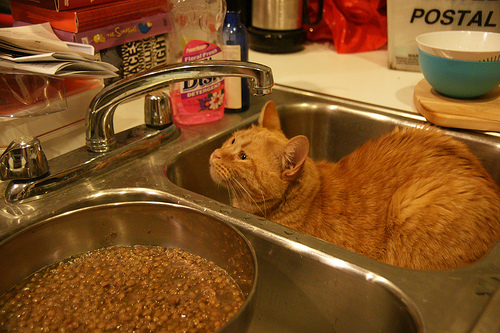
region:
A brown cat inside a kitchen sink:
[223, 111, 457, 240]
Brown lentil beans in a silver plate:
[30, 222, 293, 329]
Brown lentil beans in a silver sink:
[6, 210, 366, 331]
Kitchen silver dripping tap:
[87, 53, 277, 149]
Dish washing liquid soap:
[176, 9, 226, 124]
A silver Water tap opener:
[6, 131, 53, 180]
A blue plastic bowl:
[415, 55, 497, 97]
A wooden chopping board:
[421, 83, 498, 137]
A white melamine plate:
[416, 29, 498, 56]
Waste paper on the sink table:
[3, 26, 108, 83]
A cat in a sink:
[156, 50, 485, 301]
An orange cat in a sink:
[154, 58, 484, 271]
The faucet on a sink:
[79, 38, 319, 204]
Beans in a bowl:
[29, 192, 243, 332]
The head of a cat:
[194, 93, 330, 218]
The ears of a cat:
[257, 93, 310, 196]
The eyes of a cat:
[218, 123, 259, 172]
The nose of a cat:
[197, 139, 232, 179]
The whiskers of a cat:
[197, 149, 276, 221]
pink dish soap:
[158, 20, 244, 161]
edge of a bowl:
[244, 261, 262, 292]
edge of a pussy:
[367, 117, 439, 171]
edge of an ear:
[293, 137, 309, 192]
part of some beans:
[188, 252, 225, 297]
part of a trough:
[146, 180, 189, 229]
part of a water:
[171, 261, 203, 301]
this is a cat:
[210, 110, 448, 200]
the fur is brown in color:
[372, 149, 454, 236]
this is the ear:
[286, 131, 313, 168]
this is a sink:
[349, 275, 450, 319]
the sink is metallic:
[356, 267, 447, 325]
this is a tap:
[159, 52, 276, 102]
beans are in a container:
[69, 247, 198, 332]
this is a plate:
[416, 32, 488, 91]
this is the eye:
[238, 150, 247, 159]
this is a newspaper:
[31, 29, 82, 77]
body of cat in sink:
[331, 156, 438, 230]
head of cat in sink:
[203, 132, 313, 211]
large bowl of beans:
[110, 235, 232, 311]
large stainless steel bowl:
[199, 227, 266, 265]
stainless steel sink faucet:
[9, 75, 204, 144]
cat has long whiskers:
[233, 171, 294, 238]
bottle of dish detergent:
[178, 6, 250, 131]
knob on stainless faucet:
[6, 130, 45, 203]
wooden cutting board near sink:
[417, 70, 489, 135]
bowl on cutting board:
[408, 37, 487, 107]